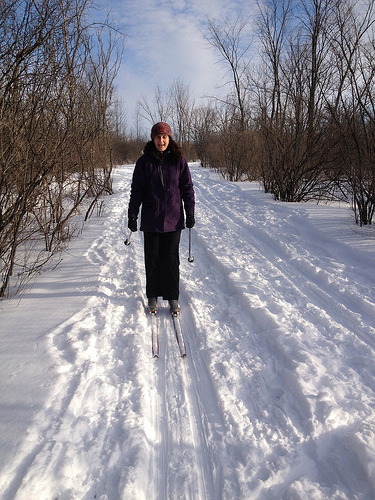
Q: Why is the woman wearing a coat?
A: Due to cold weather.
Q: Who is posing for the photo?
A: The woman.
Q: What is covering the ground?
A: Snow.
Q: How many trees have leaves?
A: 0.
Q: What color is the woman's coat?
A: Purple.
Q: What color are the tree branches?
A: Brown.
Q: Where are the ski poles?
A: In the woman's hand.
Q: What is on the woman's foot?
A: Skis.